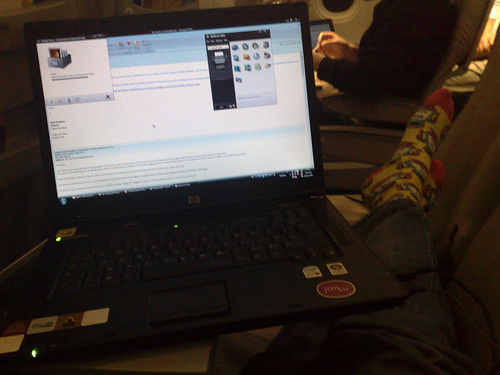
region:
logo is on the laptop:
[318, 269, 351, 299]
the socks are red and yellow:
[371, 90, 461, 196]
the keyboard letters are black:
[68, 233, 295, 267]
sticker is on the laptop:
[34, 308, 109, 332]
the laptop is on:
[25, 22, 385, 336]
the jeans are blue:
[373, 199, 453, 366]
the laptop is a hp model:
[21, 21, 402, 329]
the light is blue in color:
[26, 347, 43, 360]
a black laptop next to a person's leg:
[19, 15, 402, 349]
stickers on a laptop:
[298, 262, 357, 299]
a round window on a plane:
[313, 0, 368, 36]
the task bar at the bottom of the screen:
[58, 170, 311, 207]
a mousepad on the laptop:
[143, 276, 233, 326]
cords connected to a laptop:
[391, 265, 498, 370]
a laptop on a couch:
[19, 35, 478, 331]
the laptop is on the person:
[11, 11, 415, 356]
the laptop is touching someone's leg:
[24, 12, 421, 339]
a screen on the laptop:
[7, 9, 371, 191]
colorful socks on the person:
[370, 71, 457, 233]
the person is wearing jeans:
[355, 198, 465, 373]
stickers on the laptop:
[11, 272, 340, 374]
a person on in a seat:
[318, 11, 456, 125]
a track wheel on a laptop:
[142, 269, 247, 336]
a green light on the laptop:
[168, 209, 191, 232]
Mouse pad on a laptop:
[131, 280, 243, 331]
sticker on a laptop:
[314, 271, 359, 302]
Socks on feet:
[359, 90, 466, 216]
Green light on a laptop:
[22, 337, 61, 369]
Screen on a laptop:
[32, 32, 325, 192]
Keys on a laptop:
[58, 189, 338, 281]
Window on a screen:
[188, 22, 296, 124]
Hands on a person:
[301, 31, 361, 82]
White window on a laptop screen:
[24, 35, 136, 112]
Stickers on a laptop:
[268, 254, 406, 324]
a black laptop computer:
[22, 7, 403, 359]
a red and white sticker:
[315, 278, 355, 298]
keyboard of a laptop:
[60, 208, 334, 284]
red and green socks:
[366, 87, 458, 217]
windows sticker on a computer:
[328, 261, 348, 276]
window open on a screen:
[205, 27, 280, 112]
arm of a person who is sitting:
[314, 1, 434, 93]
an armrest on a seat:
[318, 124, 405, 164]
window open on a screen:
[34, 32, 112, 104]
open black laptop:
[20, 2, 406, 367]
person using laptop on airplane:
[311, 2, 467, 120]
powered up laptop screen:
[28, 22, 317, 200]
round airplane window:
[310, 2, 360, 22]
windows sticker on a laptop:
[324, 260, 349, 275]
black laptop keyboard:
[48, 202, 346, 297]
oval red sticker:
[312, 276, 356, 298]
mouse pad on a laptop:
[145, 276, 233, 326]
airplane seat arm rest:
[317, 92, 420, 124]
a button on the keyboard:
[160, 229, 196, 252]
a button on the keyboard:
[251, 236, 268, 253]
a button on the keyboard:
[237, 239, 254, 256]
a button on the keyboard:
[207, 229, 234, 252]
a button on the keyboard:
[270, 234, 293, 254]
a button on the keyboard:
[97, 246, 133, 258]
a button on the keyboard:
[146, 241, 165, 261]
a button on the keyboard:
[190, 236, 202, 248]